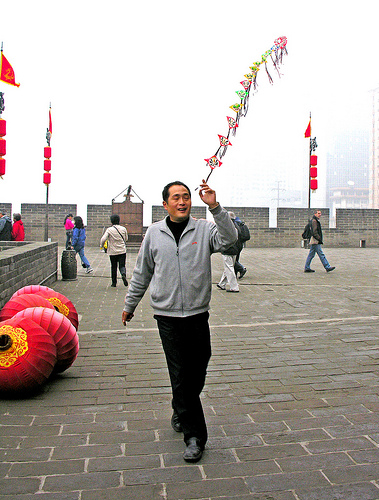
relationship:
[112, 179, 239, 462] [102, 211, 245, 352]
he wearing sweater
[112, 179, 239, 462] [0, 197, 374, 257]
he on building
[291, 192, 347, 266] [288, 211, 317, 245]
man has backpack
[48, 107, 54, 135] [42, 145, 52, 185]
flag by lanterns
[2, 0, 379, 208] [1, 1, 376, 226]
clouds in sky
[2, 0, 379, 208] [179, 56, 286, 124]
clouds in sky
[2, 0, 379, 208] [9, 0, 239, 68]
clouds in sky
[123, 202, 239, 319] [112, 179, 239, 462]
sweater on he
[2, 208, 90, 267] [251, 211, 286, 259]
people on wall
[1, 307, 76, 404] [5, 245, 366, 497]
lantern on ground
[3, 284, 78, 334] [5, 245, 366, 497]
lantern on ground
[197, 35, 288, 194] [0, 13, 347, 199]
kite in sky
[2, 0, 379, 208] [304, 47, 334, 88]
clouds in sky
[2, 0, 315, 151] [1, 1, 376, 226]
clouds in sky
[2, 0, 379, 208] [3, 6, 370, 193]
clouds in sky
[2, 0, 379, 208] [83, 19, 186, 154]
clouds in sky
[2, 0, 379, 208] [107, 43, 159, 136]
clouds in sky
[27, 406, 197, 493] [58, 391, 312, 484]
lines on ground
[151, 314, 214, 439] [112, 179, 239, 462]
pants on he